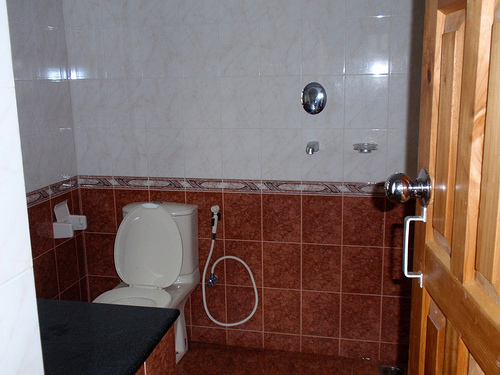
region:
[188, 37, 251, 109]
part of a wall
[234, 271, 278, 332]
part of a tubing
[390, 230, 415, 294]
part of a handle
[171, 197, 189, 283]
edge of a lid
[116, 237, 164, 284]
surface of a lid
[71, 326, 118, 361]
part of a surface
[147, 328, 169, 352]
edge of the surface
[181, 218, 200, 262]
edge of a tank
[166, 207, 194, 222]
edge of the tank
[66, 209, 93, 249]
part of a tissue holder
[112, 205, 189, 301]
a white toilet with the lid up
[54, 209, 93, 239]
a empty toilet paper dispenser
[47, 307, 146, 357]
a black counter top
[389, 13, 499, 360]
a brown door with a silver knob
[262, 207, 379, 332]
red tile wall near toilet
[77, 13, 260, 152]
white tile above toilet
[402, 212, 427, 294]
a silver handle under the knob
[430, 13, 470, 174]
wood carvings designs in door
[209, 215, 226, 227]
a black holder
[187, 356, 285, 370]
red floor matching the bottom half of the red-tiled wall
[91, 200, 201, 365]
A white toilet in a bathroom.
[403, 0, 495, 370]
A brown wood door.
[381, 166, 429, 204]
A silver door knob.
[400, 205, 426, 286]
A gray door handle.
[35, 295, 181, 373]
A black counter top.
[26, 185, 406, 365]
Red tiles on a wall.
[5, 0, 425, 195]
White tiles on a wall.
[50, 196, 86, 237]
Toilet paper roll holder.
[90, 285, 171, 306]
A white toilet bowl.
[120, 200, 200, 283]
A white toilet tank.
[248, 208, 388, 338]
the walls are brown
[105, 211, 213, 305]
the toilet is white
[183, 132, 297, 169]
the tiles are white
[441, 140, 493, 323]
the doors are brown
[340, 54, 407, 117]
there is light reflection on the wall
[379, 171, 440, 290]
the knobs are silver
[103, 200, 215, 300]
the toilet lid is up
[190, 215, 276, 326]
the hose is white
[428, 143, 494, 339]
the door is wooden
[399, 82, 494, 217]
the door is open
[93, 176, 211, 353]
a white toilet on the wall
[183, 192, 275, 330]
a white spray hose anchored to the wall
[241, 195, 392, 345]
red textured tile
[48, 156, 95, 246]
an empty toilet paper holder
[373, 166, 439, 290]
a silver and white door knob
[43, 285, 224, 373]
a black counter top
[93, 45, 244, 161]
white marbled tile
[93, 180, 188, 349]
toilet lid left up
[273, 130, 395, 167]
metal fixtures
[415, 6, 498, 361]
a wooden bathroom door left open